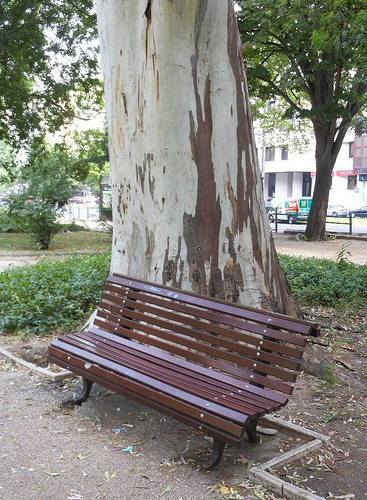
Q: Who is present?
A: No one.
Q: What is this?
A: Tree.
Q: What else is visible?
A: Bench.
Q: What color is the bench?
A: Brown.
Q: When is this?
A: Daytime.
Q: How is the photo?
A: Clear.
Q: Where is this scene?
A: At the park.